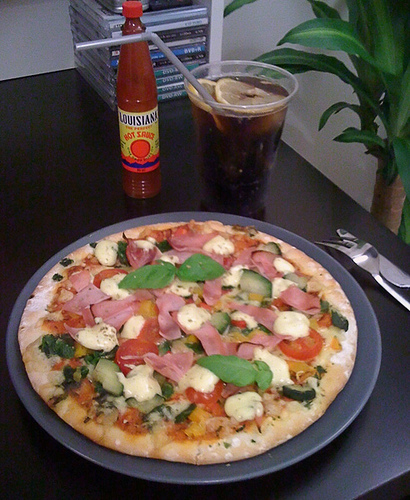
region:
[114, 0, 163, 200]
Bottle of hot sauce next to beverage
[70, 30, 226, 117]
Gray straw in beverage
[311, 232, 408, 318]
Fork next to pizza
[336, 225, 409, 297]
Knife next to fork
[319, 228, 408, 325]
Fork on black table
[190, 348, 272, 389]
Basil on round pizza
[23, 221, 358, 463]
Round pizza sitting on blue plate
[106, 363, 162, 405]
Glob of cheese on pizza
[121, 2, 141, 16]
Red cap on bottle of sauce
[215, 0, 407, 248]
Plant next to black table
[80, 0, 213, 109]
a stack of cds on a table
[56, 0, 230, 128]
a stack of cds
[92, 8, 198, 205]
a bottle of hot sauce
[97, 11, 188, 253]
a bottle of hot sauce on a table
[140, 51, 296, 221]
a plastic cup on a table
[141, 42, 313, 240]
a plastic cup with liquid in it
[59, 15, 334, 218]
a gray straw in a plastic cup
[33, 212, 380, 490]
a gray plate with a pizza on it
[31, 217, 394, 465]
a gray plate on a table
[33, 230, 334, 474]
a pizza with cheese on it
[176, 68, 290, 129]
two slices of lemon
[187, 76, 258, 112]
two slices of lemon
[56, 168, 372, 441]
a pizza on a plate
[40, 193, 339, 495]
a small pizza on a plate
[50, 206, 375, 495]
a pizza on a table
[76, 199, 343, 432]
a small pizza on a table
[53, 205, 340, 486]
a plate on a table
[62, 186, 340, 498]
a pizza uncut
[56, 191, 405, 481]
a cooked pizza on plate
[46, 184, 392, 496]
a small baked pizza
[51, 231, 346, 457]
a small cooked pizza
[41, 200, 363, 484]
a bottle of hot sauce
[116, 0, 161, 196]
Bottle of Louisiana hot sauce.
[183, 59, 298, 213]
Glass with a dark drink in it.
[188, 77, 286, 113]
Two lemons floating in a glass.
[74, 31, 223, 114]
Bending straw in a cup.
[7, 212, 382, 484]
Pizza on a metal tray.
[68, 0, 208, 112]
Sack of CDs in the background.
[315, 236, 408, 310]
Silver fork on a table.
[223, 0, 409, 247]
Fake plant in the background.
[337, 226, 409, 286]
Silver knife on a table.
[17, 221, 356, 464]
Pizza with no slices taken out.